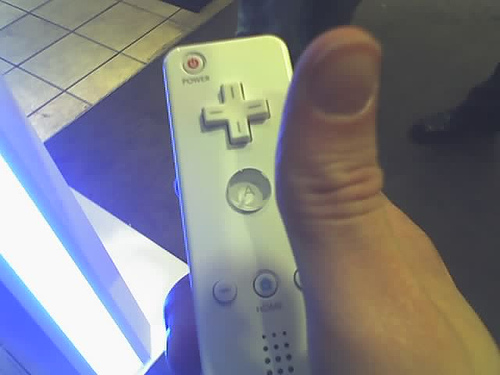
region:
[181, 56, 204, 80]
A red on/off button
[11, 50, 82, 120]
A white tile floor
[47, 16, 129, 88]
A white tile floor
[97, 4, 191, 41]
A white tile floor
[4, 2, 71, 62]
A white tile floor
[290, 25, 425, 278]
A left thumb of a human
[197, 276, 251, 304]
A white remote button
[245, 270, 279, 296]
A white remote button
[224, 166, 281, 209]
A white remote button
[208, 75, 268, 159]
A white remote button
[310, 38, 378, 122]
thumb nail on hand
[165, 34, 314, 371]
wii remote controller in hand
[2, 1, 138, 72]
tile on the ground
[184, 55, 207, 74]
power button on remote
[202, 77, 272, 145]
direction stick on remote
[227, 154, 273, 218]
a button on remote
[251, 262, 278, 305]
home button on remote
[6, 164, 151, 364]
blue neon light in room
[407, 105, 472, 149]
right foot of person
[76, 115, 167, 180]
carpet on the ground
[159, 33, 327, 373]
white plastic wii remote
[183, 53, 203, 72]
round power button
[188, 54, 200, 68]
red symbol on power button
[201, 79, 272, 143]
cross shaped button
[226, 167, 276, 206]
clear plastic button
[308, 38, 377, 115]
thumbnail attached to thumb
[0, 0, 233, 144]
white tile floor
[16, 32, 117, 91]
tile next to tile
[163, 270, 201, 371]
finger under wii remote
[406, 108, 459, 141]
black shoe on top of a dark rug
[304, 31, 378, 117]
A thumb nail of a person.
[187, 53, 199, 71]
A small power button.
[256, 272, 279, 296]
A small blue house.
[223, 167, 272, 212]
The 'A' button on the controller.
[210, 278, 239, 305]
A button with a minus sign.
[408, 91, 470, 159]
A black shoe being worn.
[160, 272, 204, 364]
A partially visible finger.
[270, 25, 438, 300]
A fully visible thumb.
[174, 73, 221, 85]
The word power on a controller.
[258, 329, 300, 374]
Small black dots on a controller.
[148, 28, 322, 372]
Nintendo Wii Controller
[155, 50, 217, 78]
Button to turn on the controller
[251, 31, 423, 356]
A person's thumb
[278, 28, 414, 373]
The thump is in the upright position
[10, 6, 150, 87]
Tile floor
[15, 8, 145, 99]
Each tile is a square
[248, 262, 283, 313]
Button to get to the home screen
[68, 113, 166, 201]
Brown carpet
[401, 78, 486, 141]
A person's foot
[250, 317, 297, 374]
The speaker on the controller